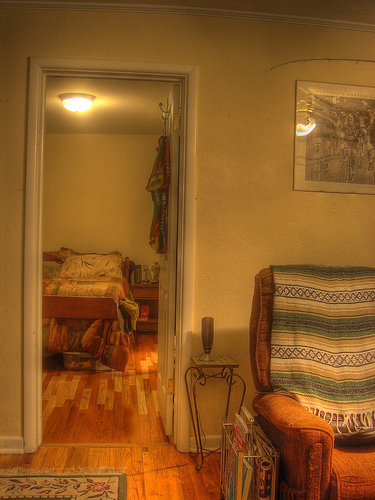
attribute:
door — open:
[148, 83, 175, 444]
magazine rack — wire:
[209, 406, 281, 500]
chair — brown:
[247, 253, 374, 497]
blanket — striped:
[270, 256, 375, 428]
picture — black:
[289, 74, 374, 209]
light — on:
[55, 91, 100, 119]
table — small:
[184, 349, 246, 471]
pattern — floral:
[84, 483, 111, 499]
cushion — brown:
[329, 440, 374, 497]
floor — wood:
[0, 328, 229, 499]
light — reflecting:
[299, 115, 316, 140]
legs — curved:
[184, 366, 213, 480]